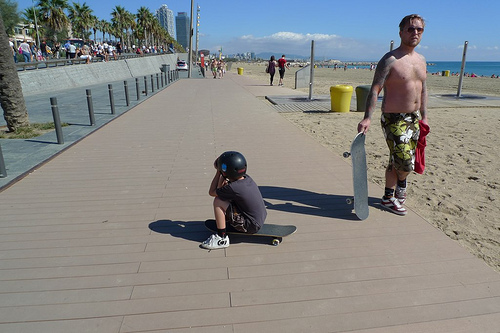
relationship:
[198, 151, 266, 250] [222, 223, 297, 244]
boy on skateboard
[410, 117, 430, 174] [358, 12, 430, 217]
shirt in man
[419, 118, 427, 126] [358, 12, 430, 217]
hand of man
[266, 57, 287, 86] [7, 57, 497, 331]
couple on boardwalk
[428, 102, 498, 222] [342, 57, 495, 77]
sand on beach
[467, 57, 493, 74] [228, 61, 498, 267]
water of beach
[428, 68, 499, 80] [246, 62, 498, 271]
people on sand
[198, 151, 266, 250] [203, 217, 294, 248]
boy on skateboard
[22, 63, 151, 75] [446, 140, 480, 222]
road above beach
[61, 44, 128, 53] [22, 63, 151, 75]
people on road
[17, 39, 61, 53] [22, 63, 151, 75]
people on road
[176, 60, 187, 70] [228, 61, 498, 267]
car at beach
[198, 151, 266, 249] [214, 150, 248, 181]
boy has helmet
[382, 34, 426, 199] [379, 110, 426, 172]
man has shorts